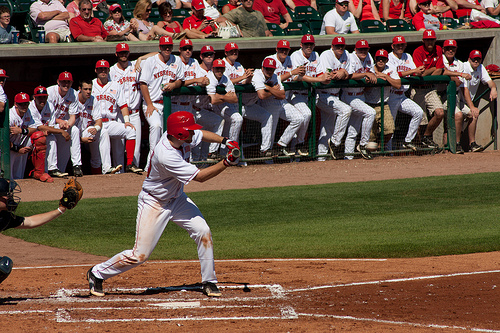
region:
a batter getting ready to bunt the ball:
[91, 110, 240, 306]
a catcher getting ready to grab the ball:
[0, 162, 83, 294]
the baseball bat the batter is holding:
[226, 144, 241, 164]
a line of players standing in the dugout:
[0, 35, 499, 173]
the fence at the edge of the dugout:
[163, 84, 462, 152]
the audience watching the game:
[1, 2, 488, 57]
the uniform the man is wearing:
[93, 130, 226, 304]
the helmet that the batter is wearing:
[162, 109, 200, 142]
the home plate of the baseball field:
[150, 294, 200, 314]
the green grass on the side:
[50, 182, 498, 261]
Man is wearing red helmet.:
[161, 109, 208, 152]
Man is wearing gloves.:
[216, 129, 247, 176]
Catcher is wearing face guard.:
[0, 170, 30, 229]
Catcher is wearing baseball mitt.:
[50, 172, 92, 218]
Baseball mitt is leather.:
[47, 175, 94, 220]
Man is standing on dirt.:
[78, 105, 252, 328]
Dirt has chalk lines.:
[16, 253, 307, 331]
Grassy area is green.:
[0, 162, 499, 264]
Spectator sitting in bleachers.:
[1, 0, 499, 45]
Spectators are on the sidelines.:
[1, 0, 498, 57]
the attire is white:
[126, 158, 225, 303]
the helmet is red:
[164, 110, 196, 135]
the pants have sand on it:
[121, 224, 170, 288]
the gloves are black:
[47, 168, 97, 217]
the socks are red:
[123, 141, 146, 167]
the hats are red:
[136, 18, 476, 61]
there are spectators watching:
[25, 21, 487, 29]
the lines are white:
[103, 290, 282, 331]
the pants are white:
[276, 101, 385, 144]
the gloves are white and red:
[224, 136, 256, 165]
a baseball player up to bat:
[82, 112, 256, 309]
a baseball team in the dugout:
[12, 28, 497, 155]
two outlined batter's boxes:
[48, 279, 314, 331]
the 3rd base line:
[289, 254, 499, 294]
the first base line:
[299, 302, 497, 332]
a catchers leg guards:
[21, 126, 61, 188]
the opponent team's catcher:
[0, 168, 90, 286]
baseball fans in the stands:
[18, 0, 498, 47]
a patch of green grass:
[92, 173, 482, 253]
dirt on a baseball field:
[0, 246, 499, 331]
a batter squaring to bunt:
[84, 111, 244, 296]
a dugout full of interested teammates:
[12, 27, 491, 168]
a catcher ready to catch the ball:
[0, 172, 82, 278]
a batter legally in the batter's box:
[52, 257, 287, 307]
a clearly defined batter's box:
[48, 268, 288, 308]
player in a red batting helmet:
[85, 110, 247, 302]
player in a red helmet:
[82, 108, 252, 297]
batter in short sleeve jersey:
[83, 112, 245, 309]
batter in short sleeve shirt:
[85, 110, 256, 299]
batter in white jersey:
[83, 109, 245, 294]